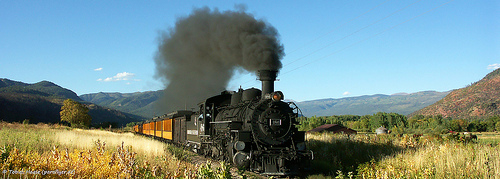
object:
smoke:
[146, 2, 287, 114]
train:
[124, 70, 316, 176]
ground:
[0, 123, 500, 179]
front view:
[229, 90, 306, 176]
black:
[217, 109, 236, 120]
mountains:
[77, 87, 169, 113]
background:
[0, 19, 499, 115]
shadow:
[299, 138, 407, 177]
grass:
[303, 131, 500, 179]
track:
[245, 169, 308, 179]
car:
[161, 112, 172, 144]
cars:
[153, 117, 161, 141]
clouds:
[91, 66, 104, 72]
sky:
[0, 0, 500, 102]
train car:
[142, 120, 147, 137]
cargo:
[132, 125, 138, 134]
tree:
[58, 98, 94, 131]